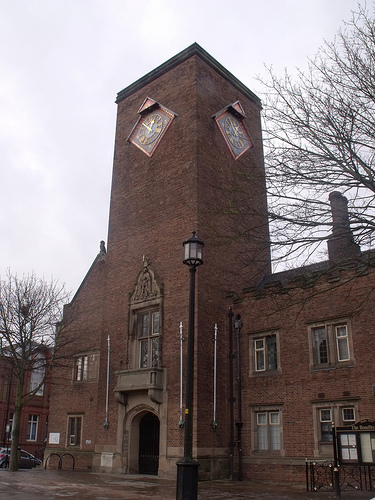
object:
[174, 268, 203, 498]
pole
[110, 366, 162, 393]
balcony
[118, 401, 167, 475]
entryway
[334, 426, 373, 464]
sign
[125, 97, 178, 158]
clock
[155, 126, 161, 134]
numbers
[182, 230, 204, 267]
light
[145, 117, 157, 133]
hand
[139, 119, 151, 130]
hand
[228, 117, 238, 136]
hand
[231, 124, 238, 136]
hand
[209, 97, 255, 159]
clock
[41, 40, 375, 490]
building